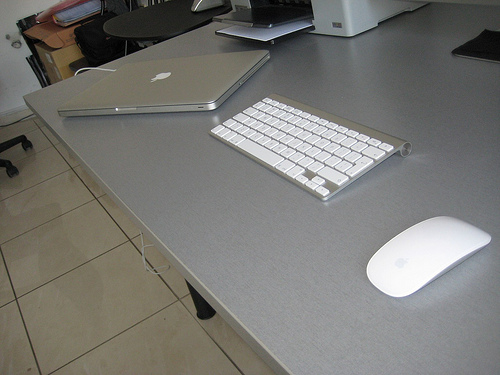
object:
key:
[276, 160, 295, 173]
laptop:
[57, 49, 270, 116]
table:
[24, 13, 499, 374]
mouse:
[365, 216, 490, 298]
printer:
[214, 2, 432, 43]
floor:
[0, 115, 295, 374]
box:
[35, 47, 83, 85]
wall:
[0, 2, 52, 124]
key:
[317, 166, 348, 185]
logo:
[151, 72, 171, 83]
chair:
[0, 133, 33, 177]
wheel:
[22, 140, 32, 150]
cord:
[74, 67, 117, 76]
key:
[208, 93, 411, 201]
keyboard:
[257, 136, 271, 145]